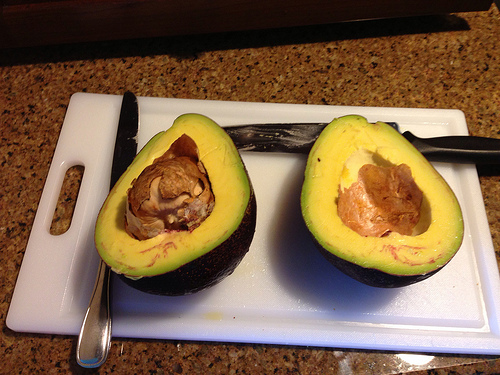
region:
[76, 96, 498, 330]
a fresh avacado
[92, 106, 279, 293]
the pit is still in place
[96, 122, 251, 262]
the inside meat is yellow/green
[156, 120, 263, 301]
the shell is green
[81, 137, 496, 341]
the cutting board is white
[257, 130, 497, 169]
the knife handle is black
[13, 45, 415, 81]
the counter is granite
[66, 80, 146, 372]
the case knife is silvery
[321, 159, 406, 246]
part of the pit hull is on the other side of the avacado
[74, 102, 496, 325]
a healthy snack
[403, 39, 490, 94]
dark brown granite countertop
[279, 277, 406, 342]
white cutting board and bottom of avocado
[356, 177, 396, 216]
skin off of pit in avocado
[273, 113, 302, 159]
knife used to cut avocado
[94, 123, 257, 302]
knife to cut avocado and one half of avocado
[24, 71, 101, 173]
corner of white cutting board and granite countertop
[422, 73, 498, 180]
knife handle, granite countertop, white cutting board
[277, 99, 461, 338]
other half of cut avocado and knife blade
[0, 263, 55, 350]
part of granite countertop and cutting board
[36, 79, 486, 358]
avocado that is cut in half and knives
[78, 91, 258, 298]
half of an avocado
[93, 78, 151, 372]
silver metal butter knife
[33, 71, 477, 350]
white plastic cutting board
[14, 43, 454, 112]
granite countertop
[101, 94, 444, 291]
two halves of an avocado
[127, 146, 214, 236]
pit of an avocado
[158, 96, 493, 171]
sharp kitchen knife that cut avocado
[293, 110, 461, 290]
yellow-green avocado with black peel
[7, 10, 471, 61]
shadow cast by something on counter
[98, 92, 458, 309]
one ripe avocado cut in half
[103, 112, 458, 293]
an avocado cut in half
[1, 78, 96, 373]
a white cutting board on a counter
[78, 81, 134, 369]
a knife on a cutting board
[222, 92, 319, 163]
a stained knife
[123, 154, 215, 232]
an avocado pit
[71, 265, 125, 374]
the silver handle of a knife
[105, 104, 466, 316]
two avocado halves on a cutting board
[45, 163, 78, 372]
a white cutting board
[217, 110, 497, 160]
a knife with a black handle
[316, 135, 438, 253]
the flesh of an avocado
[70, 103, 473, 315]
an avocado split in half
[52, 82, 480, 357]
a cutting board with avocado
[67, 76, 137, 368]
thick silver butter knife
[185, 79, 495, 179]
black handled cutting knife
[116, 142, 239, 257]
brown avocado pit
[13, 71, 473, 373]
cutting board sitting on a granite counter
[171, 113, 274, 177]
yellow and green meat of an avocado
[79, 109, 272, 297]
green avocado showing the pit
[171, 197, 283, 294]
dark green avocado skin